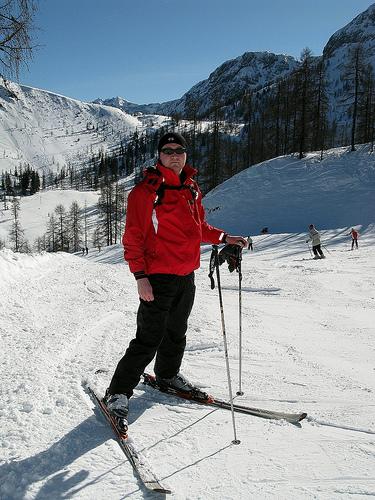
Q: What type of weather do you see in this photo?
A: It is clear.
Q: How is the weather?
A: It is clear.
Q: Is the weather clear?
A: Yes, it is clear.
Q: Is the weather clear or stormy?
A: It is clear.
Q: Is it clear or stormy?
A: It is clear.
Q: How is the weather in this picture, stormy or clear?
A: It is clear.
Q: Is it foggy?
A: No, it is clear.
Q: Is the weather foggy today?
A: No, it is clear.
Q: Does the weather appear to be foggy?
A: No, it is clear.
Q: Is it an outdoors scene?
A: Yes, it is outdoors.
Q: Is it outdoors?
A: Yes, it is outdoors.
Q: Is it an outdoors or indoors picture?
A: It is outdoors.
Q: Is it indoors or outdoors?
A: It is outdoors.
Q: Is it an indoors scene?
A: No, it is outdoors.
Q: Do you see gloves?
A: Yes, there are gloves.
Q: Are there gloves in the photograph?
A: Yes, there are gloves.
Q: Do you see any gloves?
A: Yes, there are gloves.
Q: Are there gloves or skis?
A: Yes, there are gloves.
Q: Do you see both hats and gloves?
A: Yes, there are both gloves and a hat.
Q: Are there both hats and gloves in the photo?
A: Yes, there are both gloves and a hat.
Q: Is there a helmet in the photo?
A: No, there are no helmets.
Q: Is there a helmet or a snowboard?
A: No, there are no helmets or snowboards.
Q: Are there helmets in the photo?
A: No, there are no helmets.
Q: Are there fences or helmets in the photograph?
A: No, there are no helmets or fences.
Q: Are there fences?
A: No, there are no fences.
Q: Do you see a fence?
A: No, there are no fences.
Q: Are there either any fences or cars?
A: No, there are no fences or cars.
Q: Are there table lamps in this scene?
A: No, there are no table lamps.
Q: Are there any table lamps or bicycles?
A: No, there are no table lamps or bicycles.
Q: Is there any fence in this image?
A: No, there are no fences.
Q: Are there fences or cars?
A: No, there are no fences or cars.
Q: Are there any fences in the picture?
A: No, there are no fences.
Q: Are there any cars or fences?
A: No, there are no fences or cars.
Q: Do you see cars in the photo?
A: No, there are no cars.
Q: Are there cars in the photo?
A: No, there are no cars.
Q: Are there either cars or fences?
A: No, there are no cars or fences.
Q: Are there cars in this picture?
A: No, there are no cars.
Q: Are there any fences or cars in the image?
A: No, there are no cars or fences.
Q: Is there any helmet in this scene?
A: No, there are no helmets.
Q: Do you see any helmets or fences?
A: No, there are no helmets or fences.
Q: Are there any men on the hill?
A: Yes, there is a man on the hill.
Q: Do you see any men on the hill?
A: Yes, there is a man on the hill.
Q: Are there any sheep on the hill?
A: No, there is a man on the hill.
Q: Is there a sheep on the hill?
A: No, there is a man on the hill.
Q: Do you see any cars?
A: No, there are no cars.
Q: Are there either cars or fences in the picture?
A: No, there are no cars or fences.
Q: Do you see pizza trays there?
A: No, there are no pizza trays.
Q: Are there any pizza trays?
A: No, there are no pizza trays.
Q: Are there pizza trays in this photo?
A: No, there are no pizza trays.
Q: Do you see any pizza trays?
A: No, there are no pizza trays.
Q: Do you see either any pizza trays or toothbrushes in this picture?
A: No, there are no pizza trays or toothbrushes.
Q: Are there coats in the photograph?
A: Yes, there is a coat.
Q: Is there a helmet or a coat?
A: Yes, there is a coat.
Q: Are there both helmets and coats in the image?
A: No, there is a coat but no helmets.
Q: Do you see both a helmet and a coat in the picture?
A: No, there is a coat but no helmets.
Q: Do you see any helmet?
A: No, there are no helmets.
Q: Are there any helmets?
A: No, there are no helmets.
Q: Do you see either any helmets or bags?
A: No, there are no helmets or bags.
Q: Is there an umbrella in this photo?
A: No, there are no umbrellas.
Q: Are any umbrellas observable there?
A: No, there are no umbrellas.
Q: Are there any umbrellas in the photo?
A: No, there are no umbrellas.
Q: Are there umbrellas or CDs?
A: No, there are no umbrellas or cds.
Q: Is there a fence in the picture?
A: No, there are no fences.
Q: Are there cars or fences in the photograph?
A: No, there are no fences or cars.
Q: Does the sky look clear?
A: Yes, the sky is clear.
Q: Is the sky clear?
A: Yes, the sky is clear.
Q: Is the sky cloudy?
A: No, the sky is clear.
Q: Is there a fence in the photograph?
A: No, there are no fences.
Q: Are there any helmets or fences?
A: No, there are no fences or helmets.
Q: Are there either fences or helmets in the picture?
A: No, there are no fences or helmets.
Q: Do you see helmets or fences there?
A: No, there are no fences or helmets.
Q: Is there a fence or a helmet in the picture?
A: No, there are no fences or helmets.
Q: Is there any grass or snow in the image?
A: Yes, there is snow.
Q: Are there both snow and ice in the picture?
A: No, there is snow but no ice.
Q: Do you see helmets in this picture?
A: No, there are no helmets.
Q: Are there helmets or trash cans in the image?
A: No, there are no helmets or trash cans.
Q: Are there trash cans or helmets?
A: No, there are no helmets or trash cans.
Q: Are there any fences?
A: No, there are no fences.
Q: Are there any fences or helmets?
A: No, there are no fences or helmets.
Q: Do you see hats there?
A: Yes, there is a hat.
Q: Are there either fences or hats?
A: Yes, there is a hat.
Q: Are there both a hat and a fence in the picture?
A: No, there is a hat but no fences.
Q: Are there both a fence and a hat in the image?
A: No, there is a hat but no fences.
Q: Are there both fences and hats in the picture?
A: No, there is a hat but no fences.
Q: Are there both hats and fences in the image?
A: No, there is a hat but no fences.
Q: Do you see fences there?
A: No, there are no fences.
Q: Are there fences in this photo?
A: No, there are no fences.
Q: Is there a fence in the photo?
A: No, there are no fences.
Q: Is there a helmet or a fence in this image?
A: No, there are no fences or helmets.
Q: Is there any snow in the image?
A: Yes, there is snow.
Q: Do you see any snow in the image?
A: Yes, there is snow.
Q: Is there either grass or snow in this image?
A: Yes, there is snow.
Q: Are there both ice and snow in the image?
A: No, there is snow but no ice.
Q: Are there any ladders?
A: No, there are no ladders.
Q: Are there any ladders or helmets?
A: No, there are no ladders or helmets.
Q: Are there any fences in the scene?
A: No, there are no fences.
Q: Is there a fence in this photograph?
A: No, there are no fences.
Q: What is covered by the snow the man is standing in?
A: The ground is covered by the snow.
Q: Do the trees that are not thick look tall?
A: Yes, the trees are tall.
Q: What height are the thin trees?
A: The trees are tall.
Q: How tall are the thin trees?
A: The trees are tall.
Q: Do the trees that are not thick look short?
A: No, the trees are tall.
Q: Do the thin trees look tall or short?
A: The trees are tall.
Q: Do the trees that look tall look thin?
A: Yes, the trees are thin.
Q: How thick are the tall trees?
A: The trees are thin.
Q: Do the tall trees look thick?
A: No, the trees are thin.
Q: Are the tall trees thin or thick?
A: The trees are thin.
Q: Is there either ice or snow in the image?
A: Yes, there is snow.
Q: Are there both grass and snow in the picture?
A: No, there is snow but no grass.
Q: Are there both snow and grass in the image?
A: No, there is snow but no grass.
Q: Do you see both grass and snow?
A: No, there is snow but no grass.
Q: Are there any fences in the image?
A: No, there are no fences.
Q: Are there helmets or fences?
A: No, there are no fences or helmets.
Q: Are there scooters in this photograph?
A: No, there are no scooters.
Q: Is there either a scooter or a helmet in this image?
A: No, there are no scooters or helmets.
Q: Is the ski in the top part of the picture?
A: No, the ski is in the bottom of the image.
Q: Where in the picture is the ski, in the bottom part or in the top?
A: The ski is in the bottom of the image.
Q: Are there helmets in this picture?
A: No, there are no helmets.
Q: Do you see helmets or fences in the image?
A: No, there are no helmets or fences.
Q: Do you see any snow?
A: Yes, there is snow.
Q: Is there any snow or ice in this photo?
A: Yes, there is snow.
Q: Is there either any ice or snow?
A: Yes, there is snow.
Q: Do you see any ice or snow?
A: Yes, there is snow.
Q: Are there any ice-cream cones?
A: No, there are no ice-cream cones.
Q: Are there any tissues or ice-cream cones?
A: No, there are no ice-cream cones or tissues.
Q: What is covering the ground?
A: The snow is covering the ground.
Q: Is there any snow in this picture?
A: Yes, there is snow.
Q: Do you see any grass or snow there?
A: Yes, there is snow.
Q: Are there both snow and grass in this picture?
A: No, there is snow but no grass.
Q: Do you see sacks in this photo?
A: No, there are no sacks.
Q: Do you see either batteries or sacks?
A: No, there are no sacks or batteries.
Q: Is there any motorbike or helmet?
A: No, there are no helmets or motorcycles.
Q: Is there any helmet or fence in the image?
A: No, there are no fences or helmets.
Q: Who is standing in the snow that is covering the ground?
A: The man is standing in the snow.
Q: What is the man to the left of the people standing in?
A: The man is standing in the snow.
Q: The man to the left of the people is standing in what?
A: The man is standing in the snow.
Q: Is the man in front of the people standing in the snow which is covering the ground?
A: Yes, the man is standing in the snow.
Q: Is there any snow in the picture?
A: Yes, there is snow.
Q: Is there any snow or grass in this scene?
A: Yes, there is snow.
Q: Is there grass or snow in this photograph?
A: Yes, there is snow.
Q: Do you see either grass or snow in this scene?
A: Yes, there is snow.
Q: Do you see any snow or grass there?
A: Yes, there is snow.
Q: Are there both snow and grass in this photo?
A: No, there is snow but no grass.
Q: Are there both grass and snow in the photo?
A: No, there is snow but no grass.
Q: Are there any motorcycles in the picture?
A: No, there are no motorcycles.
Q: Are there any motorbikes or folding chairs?
A: No, there are no motorbikes or folding chairs.